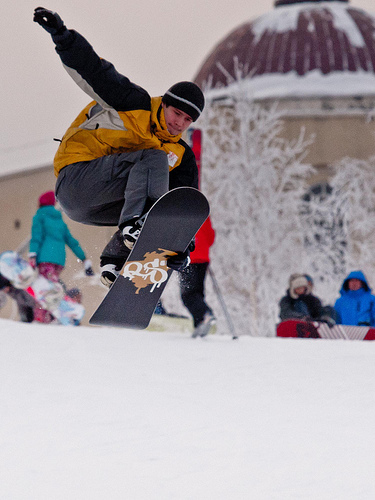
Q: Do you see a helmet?
A: No, there are no helmets.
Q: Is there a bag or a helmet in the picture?
A: No, there are no helmets or bags.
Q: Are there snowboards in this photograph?
A: Yes, there is a snowboard.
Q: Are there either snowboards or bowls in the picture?
A: Yes, there is a snowboard.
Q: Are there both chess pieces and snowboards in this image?
A: No, there is a snowboard but no chess pieces.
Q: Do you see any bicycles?
A: No, there are no bicycles.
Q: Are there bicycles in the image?
A: No, there are no bicycles.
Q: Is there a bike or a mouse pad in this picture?
A: No, there are no bikes or mouse pads.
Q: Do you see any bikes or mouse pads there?
A: No, there are no bikes or mouse pads.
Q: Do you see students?
A: No, there are no students.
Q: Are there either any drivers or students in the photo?
A: No, there are no students or drivers.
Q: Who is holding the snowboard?
A: The man is holding the snowboard.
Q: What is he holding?
A: The man is holding the snow board.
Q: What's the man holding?
A: The man is holding the snow board.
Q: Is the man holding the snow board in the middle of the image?
A: Yes, the man is holding the snowboard.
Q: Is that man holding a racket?
A: No, the man is holding the snowboard.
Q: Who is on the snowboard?
A: The man is on the snowboard.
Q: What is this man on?
A: The man is on the snowboard.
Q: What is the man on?
A: The man is on the snowboard.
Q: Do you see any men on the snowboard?
A: Yes, there is a man on the snowboard.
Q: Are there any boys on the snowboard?
A: No, there is a man on the snowboard.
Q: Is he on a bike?
A: No, the man is on the snowboard.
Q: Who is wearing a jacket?
A: The man is wearing a jacket.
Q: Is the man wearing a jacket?
A: Yes, the man is wearing a jacket.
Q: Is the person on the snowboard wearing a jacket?
A: Yes, the man is wearing a jacket.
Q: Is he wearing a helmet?
A: No, the man is wearing a jacket.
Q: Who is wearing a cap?
A: The man is wearing a cap.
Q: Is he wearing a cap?
A: Yes, the man is wearing a cap.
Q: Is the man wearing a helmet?
A: No, the man is wearing a cap.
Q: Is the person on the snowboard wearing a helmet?
A: No, the man is wearing a cap.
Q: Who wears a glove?
A: The man wears a glove.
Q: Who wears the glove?
A: The man wears a glove.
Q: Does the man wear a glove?
A: Yes, the man wears a glove.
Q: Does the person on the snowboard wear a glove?
A: Yes, the man wears a glove.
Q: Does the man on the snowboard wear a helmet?
A: No, the man wears a glove.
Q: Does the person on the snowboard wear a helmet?
A: No, the man wears a glove.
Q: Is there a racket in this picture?
A: No, there are no rackets.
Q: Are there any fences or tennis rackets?
A: No, there are no tennis rackets or fences.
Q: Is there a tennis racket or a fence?
A: No, there are no rackets or fences.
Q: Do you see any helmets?
A: No, there are no helmets.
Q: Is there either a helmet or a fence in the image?
A: No, there are no helmets or fences.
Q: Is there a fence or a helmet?
A: No, there are no helmets or fences.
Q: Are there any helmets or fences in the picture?
A: No, there are no helmets or fences.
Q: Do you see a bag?
A: No, there are no bags.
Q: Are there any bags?
A: No, there are no bags.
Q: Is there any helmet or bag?
A: No, there are no bags or helmets.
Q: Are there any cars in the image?
A: No, there are no cars.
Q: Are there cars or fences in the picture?
A: No, there are no cars or fences.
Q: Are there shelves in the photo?
A: No, there are no shelves.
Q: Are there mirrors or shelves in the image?
A: No, there are no shelves or mirrors.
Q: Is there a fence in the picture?
A: No, there are no fences.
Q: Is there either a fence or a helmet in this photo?
A: No, there are no fences or helmets.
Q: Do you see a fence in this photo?
A: No, there are no fences.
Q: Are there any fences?
A: No, there are no fences.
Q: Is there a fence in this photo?
A: No, there are no fences.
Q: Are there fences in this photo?
A: No, there are no fences.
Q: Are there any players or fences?
A: No, there are no fences or players.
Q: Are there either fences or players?
A: No, there are no fences or players.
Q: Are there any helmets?
A: No, there are no helmets.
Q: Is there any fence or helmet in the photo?
A: No, there are no helmets or fences.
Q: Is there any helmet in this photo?
A: No, there are no helmets.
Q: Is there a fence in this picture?
A: No, there are no fences.